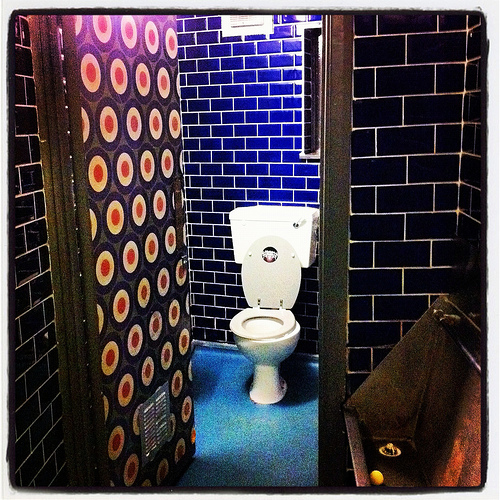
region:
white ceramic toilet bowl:
[220, 190, 310, 430]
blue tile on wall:
[352, 148, 412, 198]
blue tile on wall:
[188, 179, 223, 210]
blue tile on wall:
[232, 143, 257, 170]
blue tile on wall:
[192, 132, 230, 159]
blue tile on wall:
[231, 95, 263, 119]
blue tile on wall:
[210, 68, 238, 89]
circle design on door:
[115, 228, 179, 278]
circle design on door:
[98, 108, 159, 149]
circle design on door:
[77, 46, 138, 100]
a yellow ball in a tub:
[367, 468, 384, 486]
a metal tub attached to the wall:
[342, 281, 484, 497]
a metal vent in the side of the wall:
[132, 378, 179, 464]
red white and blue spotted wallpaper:
[63, 15, 221, 485]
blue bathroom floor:
[167, 333, 324, 490]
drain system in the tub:
[378, 440, 403, 458]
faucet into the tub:
[430, 305, 460, 330]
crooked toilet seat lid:
[227, 304, 295, 341]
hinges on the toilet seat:
[252, 299, 287, 310]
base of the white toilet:
[242, 363, 294, 404]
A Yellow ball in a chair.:
[367, 463, 387, 487]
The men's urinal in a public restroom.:
[350, 305, 478, 489]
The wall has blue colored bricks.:
[359, 108, 453, 288]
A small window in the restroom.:
[298, 30, 323, 157]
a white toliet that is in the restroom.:
[228, 208, 305, 413]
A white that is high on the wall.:
[218, 15, 275, 26]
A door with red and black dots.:
[85, 119, 190, 341]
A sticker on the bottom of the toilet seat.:
[263, 242, 279, 272]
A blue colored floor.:
[218, 420, 288, 477]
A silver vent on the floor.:
[139, 393, 183, 468]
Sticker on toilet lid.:
[262, 242, 297, 286]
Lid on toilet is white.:
[245, 263, 297, 293]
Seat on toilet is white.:
[237, 318, 290, 342]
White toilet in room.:
[246, 353, 301, 402]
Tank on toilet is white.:
[236, 197, 315, 241]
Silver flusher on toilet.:
[286, 218, 317, 235]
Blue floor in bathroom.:
[203, 366, 255, 483]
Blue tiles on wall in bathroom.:
[226, 157, 278, 195]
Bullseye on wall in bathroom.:
[105, 228, 165, 320]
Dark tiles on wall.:
[363, 233, 406, 272]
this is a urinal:
[345, 294, 497, 499]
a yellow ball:
[365, 465, 384, 484]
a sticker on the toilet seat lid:
[257, 245, 282, 265]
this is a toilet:
[218, 185, 316, 408]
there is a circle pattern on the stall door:
[73, 11, 202, 489]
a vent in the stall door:
[120, 375, 175, 462]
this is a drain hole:
[378, 438, 402, 460]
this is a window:
[303, 25, 321, 153]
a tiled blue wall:
[178, 16, 318, 363]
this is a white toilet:
[218, 183, 318, 409]